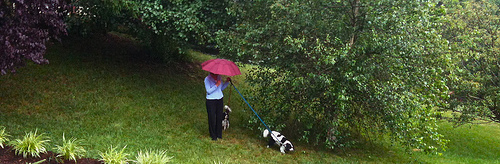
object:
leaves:
[30, 46, 53, 63]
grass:
[317, 143, 489, 162]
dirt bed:
[6, 141, 106, 161]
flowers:
[1, 120, 174, 162]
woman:
[204, 72, 229, 140]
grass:
[1, 32, 498, 162]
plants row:
[2, 122, 182, 162]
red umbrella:
[200, 59, 241, 75]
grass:
[11, 44, 206, 156]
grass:
[423, 112, 498, 162]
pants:
[205, 100, 230, 138]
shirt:
[202, 74, 232, 101]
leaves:
[279, 31, 435, 118]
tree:
[80, 22, 490, 142]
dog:
[258, 123, 295, 153]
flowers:
[0, 24, 62, 93]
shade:
[78, 33, 188, 111]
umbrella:
[199, 52, 244, 79]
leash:
[229, 82, 284, 143]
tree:
[236, 2, 458, 162]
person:
[194, 72, 259, 133]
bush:
[234, 7, 482, 159]